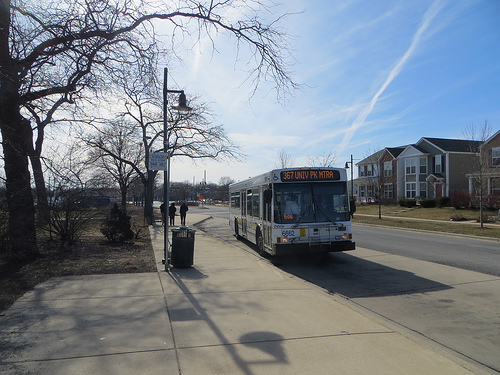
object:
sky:
[0, 0, 499, 190]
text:
[283, 171, 334, 179]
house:
[355, 128, 500, 209]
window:
[435, 155, 441, 173]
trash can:
[170, 226, 196, 268]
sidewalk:
[1, 212, 494, 374]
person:
[180, 201, 188, 226]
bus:
[228, 166, 357, 257]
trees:
[1, 0, 317, 256]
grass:
[350, 203, 500, 239]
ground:
[1, 199, 500, 374]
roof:
[411, 137, 488, 155]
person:
[169, 203, 176, 226]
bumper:
[274, 241, 357, 254]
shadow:
[165, 268, 290, 372]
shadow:
[235, 234, 456, 298]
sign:
[149, 152, 167, 171]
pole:
[165, 151, 171, 271]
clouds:
[0, 0, 499, 186]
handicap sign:
[273, 174, 280, 181]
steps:
[385, 206, 422, 214]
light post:
[170, 94, 193, 112]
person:
[160, 203, 165, 226]